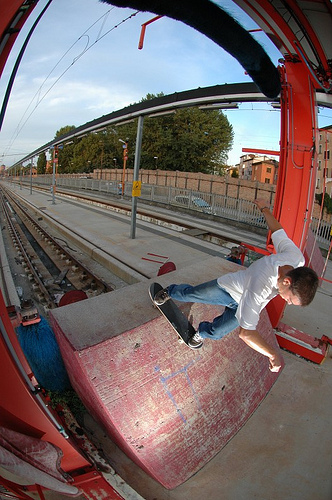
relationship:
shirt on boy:
[221, 229, 305, 332] [150, 199, 317, 375]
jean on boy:
[163, 283, 235, 304] [150, 199, 317, 375]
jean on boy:
[201, 307, 240, 341] [150, 199, 317, 375]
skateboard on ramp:
[148, 282, 202, 348] [50, 313, 285, 487]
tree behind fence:
[144, 93, 234, 177] [94, 170, 201, 185]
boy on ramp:
[150, 199, 317, 375] [50, 313, 285, 487]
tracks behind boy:
[1, 183, 111, 306] [150, 199, 317, 375]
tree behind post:
[59, 126, 124, 174] [130, 115, 144, 240]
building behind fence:
[239, 155, 252, 181] [94, 170, 201, 185]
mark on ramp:
[156, 363, 191, 388] [50, 313, 285, 487]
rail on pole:
[105, 84, 257, 128] [50, 146, 56, 209]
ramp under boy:
[50, 313, 285, 487] [150, 199, 317, 375]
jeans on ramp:
[171, 278, 243, 339] [50, 313, 285, 487]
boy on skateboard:
[150, 199, 317, 375] [148, 282, 202, 348]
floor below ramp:
[238, 432, 332, 498] [50, 313, 285, 487]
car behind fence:
[172, 190, 214, 215] [55, 179, 260, 229]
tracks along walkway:
[1, 183, 111, 306] [2, 183, 210, 275]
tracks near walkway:
[1, 183, 111, 306] [2, 183, 210, 275]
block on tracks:
[59, 291, 88, 314] [1, 183, 111, 306]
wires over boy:
[3, 3, 131, 151] [150, 199, 317, 375]